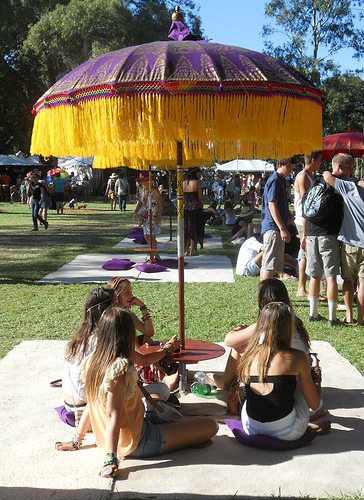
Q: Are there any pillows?
A: Yes, there is a pillow.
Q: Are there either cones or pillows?
A: Yes, there is a pillow.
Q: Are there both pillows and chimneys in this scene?
A: No, there is a pillow but no chimneys.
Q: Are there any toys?
A: No, there are no toys.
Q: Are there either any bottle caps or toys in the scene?
A: No, there are no toys or bottle caps.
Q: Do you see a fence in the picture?
A: No, there are no fences.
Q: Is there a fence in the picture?
A: No, there are no fences.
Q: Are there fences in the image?
A: No, there are no fences.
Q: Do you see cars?
A: No, there are no cars.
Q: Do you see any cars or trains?
A: No, there are no cars or trains.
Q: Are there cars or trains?
A: No, there are no cars or trains.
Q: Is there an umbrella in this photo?
A: Yes, there is an umbrella.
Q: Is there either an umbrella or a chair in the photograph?
A: Yes, there is an umbrella.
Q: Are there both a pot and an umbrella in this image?
A: No, there is an umbrella but no pots.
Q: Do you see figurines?
A: No, there are no figurines.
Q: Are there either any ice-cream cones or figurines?
A: No, there are no figurines or ice-cream cones.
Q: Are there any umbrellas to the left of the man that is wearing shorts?
A: Yes, there is an umbrella to the left of the man.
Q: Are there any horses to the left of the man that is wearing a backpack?
A: No, there is an umbrella to the left of the man.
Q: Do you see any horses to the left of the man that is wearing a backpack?
A: No, there is an umbrella to the left of the man.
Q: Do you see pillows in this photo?
A: Yes, there is a pillow.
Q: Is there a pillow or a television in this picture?
A: Yes, there is a pillow.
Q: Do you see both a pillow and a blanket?
A: Yes, there are both a pillow and a blanket.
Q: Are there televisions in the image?
A: No, there are no televisions.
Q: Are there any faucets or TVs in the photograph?
A: No, there are no TVs or faucets.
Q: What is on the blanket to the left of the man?
A: The pillow is on the blanket.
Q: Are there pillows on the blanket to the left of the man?
A: Yes, there is a pillow on the blanket.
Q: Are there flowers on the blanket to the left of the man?
A: No, there is a pillow on the blanket.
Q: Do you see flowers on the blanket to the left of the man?
A: No, there is a pillow on the blanket.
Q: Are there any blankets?
A: Yes, there is a blanket.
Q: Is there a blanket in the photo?
A: Yes, there is a blanket.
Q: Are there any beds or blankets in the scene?
A: Yes, there is a blanket.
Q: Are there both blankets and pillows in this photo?
A: Yes, there are both a blanket and a pillow.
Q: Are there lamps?
A: No, there are no lamps.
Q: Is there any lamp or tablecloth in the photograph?
A: No, there are no lamps or tablecloths.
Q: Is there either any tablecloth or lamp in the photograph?
A: No, there are no lamps or tablecloths.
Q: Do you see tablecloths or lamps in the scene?
A: No, there are no lamps or tablecloths.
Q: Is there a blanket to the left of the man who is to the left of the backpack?
A: Yes, there is a blanket to the left of the man.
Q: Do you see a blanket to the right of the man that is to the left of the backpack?
A: No, the blanket is to the left of the man.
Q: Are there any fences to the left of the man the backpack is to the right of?
A: No, there is a blanket to the left of the man.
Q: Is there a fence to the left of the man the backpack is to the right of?
A: No, there is a blanket to the left of the man.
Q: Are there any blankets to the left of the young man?
A: Yes, there is a blanket to the left of the man.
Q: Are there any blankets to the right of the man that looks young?
A: No, the blanket is to the left of the man.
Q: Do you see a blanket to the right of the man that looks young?
A: No, the blanket is to the left of the man.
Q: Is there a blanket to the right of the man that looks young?
A: No, the blanket is to the left of the man.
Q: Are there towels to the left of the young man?
A: No, there is a blanket to the left of the man.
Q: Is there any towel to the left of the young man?
A: No, there is a blanket to the left of the man.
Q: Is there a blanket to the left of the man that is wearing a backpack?
A: Yes, there is a blanket to the left of the man.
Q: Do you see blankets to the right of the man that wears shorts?
A: No, the blanket is to the left of the man.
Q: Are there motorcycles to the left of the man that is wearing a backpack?
A: No, there is a blanket to the left of the man.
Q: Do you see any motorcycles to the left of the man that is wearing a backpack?
A: No, there is a blanket to the left of the man.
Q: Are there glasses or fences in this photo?
A: No, there are no fences or glasses.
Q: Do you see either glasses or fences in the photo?
A: No, there are no fences or glasses.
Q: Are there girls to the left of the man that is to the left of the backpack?
A: Yes, there is a girl to the left of the man.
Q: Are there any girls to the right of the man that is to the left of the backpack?
A: No, the girl is to the left of the man.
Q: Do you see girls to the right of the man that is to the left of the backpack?
A: No, the girl is to the left of the man.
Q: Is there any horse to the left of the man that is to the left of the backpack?
A: No, there is a girl to the left of the man.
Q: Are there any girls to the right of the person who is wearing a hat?
A: Yes, there is a girl to the right of the person.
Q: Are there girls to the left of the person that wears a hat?
A: No, the girl is to the right of the person.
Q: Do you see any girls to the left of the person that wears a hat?
A: No, the girl is to the right of the person.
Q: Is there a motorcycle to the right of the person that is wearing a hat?
A: No, there is a girl to the right of the person.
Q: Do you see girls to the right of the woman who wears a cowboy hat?
A: Yes, there is a girl to the right of the woman.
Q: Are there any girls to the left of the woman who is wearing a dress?
A: No, the girl is to the right of the woman.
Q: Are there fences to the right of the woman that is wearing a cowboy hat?
A: No, there is a girl to the right of the woman.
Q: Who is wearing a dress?
A: The girl is wearing a dress.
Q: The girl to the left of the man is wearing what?
A: The girl is wearing a dress.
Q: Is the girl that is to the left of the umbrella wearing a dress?
A: Yes, the girl is wearing a dress.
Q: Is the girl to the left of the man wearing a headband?
A: No, the girl is wearing a dress.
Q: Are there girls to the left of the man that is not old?
A: Yes, there is a girl to the left of the man.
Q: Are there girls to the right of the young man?
A: No, the girl is to the left of the man.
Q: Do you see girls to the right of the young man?
A: No, the girl is to the left of the man.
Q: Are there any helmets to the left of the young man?
A: No, there is a girl to the left of the man.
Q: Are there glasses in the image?
A: No, there are no glasses.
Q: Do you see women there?
A: Yes, there is a woman.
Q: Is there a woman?
A: Yes, there is a woman.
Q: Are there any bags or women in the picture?
A: Yes, there is a woman.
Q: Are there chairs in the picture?
A: No, there are no chairs.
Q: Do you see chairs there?
A: No, there are no chairs.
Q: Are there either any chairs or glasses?
A: No, there are no chairs or glasses.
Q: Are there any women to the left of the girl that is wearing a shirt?
A: Yes, there is a woman to the left of the girl.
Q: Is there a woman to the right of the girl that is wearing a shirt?
A: No, the woman is to the left of the girl.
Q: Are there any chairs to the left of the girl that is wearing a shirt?
A: No, there is a woman to the left of the girl.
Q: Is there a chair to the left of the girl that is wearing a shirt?
A: No, there is a woman to the left of the girl.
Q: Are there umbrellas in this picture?
A: Yes, there is an umbrella.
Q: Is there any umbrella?
A: Yes, there is an umbrella.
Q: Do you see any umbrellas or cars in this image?
A: Yes, there is an umbrella.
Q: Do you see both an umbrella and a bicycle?
A: No, there is an umbrella but no bicycles.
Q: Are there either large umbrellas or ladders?
A: Yes, there is a large umbrella.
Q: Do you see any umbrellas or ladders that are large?
A: Yes, the umbrella is large.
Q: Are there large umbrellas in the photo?
A: Yes, there is a large umbrella.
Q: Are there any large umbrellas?
A: Yes, there is a large umbrella.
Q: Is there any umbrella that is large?
A: Yes, there is an umbrella that is large.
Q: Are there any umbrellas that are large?
A: Yes, there is an umbrella that is large.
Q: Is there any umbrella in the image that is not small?
A: Yes, there is a large umbrella.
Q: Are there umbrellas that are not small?
A: Yes, there is a large umbrella.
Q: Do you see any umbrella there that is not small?
A: Yes, there is a large umbrella.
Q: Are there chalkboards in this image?
A: No, there are no chalkboards.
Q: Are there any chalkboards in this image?
A: No, there are no chalkboards.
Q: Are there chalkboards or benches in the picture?
A: No, there are no chalkboards or benches.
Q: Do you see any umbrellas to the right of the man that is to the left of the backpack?
A: No, the umbrella is to the left of the man.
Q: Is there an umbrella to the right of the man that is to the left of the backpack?
A: No, the umbrella is to the left of the man.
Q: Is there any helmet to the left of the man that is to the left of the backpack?
A: No, there is an umbrella to the left of the man.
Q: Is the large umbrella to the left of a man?
A: Yes, the umbrella is to the left of a man.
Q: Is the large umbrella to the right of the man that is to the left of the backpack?
A: No, the umbrella is to the left of the man.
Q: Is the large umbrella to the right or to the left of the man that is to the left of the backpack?
A: The umbrella is to the left of the man.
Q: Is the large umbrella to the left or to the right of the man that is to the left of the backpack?
A: The umbrella is to the left of the man.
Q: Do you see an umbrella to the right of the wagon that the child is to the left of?
A: Yes, there is an umbrella to the right of the wagon.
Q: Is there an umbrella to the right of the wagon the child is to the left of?
A: Yes, there is an umbrella to the right of the wagon.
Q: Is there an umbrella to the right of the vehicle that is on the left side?
A: Yes, there is an umbrella to the right of the wagon.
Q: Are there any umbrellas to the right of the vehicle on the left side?
A: Yes, there is an umbrella to the right of the wagon.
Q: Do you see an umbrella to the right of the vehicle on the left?
A: Yes, there is an umbrella to the right of the wagon.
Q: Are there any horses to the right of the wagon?
A: No, there is an umbrella to the right of the wagon.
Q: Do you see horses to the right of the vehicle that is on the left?
A: No, there is an umbrella to the right of the wagon.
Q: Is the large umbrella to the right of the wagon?
A: Yes, the umbrella is to the right of the wagon.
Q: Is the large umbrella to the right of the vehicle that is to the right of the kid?
A: Yes, the umbrella is to the right of the wagon.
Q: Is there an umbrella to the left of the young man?
A: Yes, there is an umbrella to the left of the man.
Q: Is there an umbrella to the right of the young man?
A: No, the umbrella is to the left of the man.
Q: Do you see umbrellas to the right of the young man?
A: No, the umbrella is to the left of the man.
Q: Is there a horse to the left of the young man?
A: No, there is an umbrella to the left of the man.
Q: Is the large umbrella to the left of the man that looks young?
A: Yes, the umbrella is to the left of the man.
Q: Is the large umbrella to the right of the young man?
A: No, the umbrella is to the left of the man.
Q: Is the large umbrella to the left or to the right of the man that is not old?
A: The umbrella is to the left of the man.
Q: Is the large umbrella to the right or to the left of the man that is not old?
A: The umbrella is to the left of the man.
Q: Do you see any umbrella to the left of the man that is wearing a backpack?
A: Yes, there is an umbrella to the left of the man.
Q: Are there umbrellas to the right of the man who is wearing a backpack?
A: No, the umbrella is to the left of the man.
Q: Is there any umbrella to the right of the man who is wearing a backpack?
A: No, the umbrella is to the left of the man.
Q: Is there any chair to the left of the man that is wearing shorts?
A: No, there is an umbrella to the left of the man.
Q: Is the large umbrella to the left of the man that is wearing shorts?
A: Yes, the umbrella is to the left of the man.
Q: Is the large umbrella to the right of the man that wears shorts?
A: No, the umbrella is to the left of the man.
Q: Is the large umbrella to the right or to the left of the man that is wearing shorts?
A: The umbrella is to the left of the man.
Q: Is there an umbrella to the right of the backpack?
A: No, the umbrella is to the left of the backpack.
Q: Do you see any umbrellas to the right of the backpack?
A: No, the umbrella is to the left of the backpack.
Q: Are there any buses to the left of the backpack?
A: No, there is an umbrella to the left of the backpack.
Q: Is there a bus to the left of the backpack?
A: No, there is an umbrella to the left of the backpack.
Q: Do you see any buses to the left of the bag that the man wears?
A: No, there is an umbrella to the left of the backpack.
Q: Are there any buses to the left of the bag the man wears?
A: No, there is an umbrella to the left of the backpack.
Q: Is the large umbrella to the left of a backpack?
A: Yes, the umbrella is to the left of a backpack.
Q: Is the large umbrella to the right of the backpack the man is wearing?
A: No, the umbrella is to the left of the backpack.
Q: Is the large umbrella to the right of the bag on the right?
A: No, the umbrella is to the left of the backpack.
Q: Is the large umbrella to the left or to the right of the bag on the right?
A: The umbrella is to the left of the backpack.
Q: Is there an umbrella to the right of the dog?
A: Yes, there is an umbrella to the right of the dog.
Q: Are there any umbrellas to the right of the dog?
A: Yes, there is an umbrella to the right of the dog.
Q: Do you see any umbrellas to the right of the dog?
A: Yes, there is an umbrella to the right of the dog.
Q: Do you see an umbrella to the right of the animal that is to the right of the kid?
A: Yes, there is an umbrella to the right of the dog.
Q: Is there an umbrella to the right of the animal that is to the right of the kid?
A: Yes, there is an umbrella to the right of the dog.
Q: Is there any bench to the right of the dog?
A: No, there is an umbrella to the right of the dog.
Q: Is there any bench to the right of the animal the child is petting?
A: No, there is an umbrella to the right of the dog.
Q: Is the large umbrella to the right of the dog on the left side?
A: Yes, the umbrella is to the right of the dog.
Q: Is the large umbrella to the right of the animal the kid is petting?
A: Yes, the umbrella is to the right of the dog.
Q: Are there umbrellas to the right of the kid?
A: Yes, there is an umbrella to the right of the kid.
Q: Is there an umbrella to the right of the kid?
A: Yes, there is an umbrella to the right of the kid.